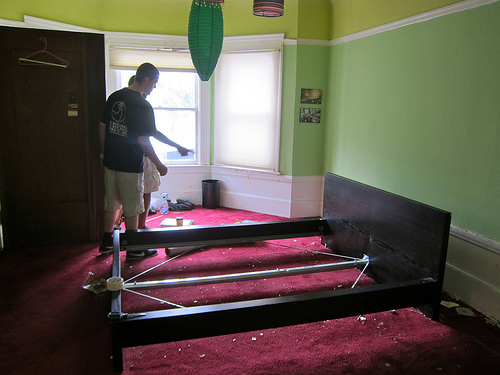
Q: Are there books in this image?
A: No, there are no books.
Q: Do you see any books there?
A: No, there are no books.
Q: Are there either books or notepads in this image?
A: No, there are no books or notepads.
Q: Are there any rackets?
A: No, there are no rackets.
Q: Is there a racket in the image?
A: No, there are no rackets.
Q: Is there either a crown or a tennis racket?
A: No, there are no rackets or crowns.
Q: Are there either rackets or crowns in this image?
A: No, there are no rackets or crowns.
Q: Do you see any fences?
A: No, there are no fences.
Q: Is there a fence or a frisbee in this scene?
A: No, there are no fences or frisbees.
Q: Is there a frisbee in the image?
A: No, there are no frisbees.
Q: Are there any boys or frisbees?
A: No, there are no frisbees or boys.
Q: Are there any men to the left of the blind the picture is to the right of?
A: Yes, there is a man to the left of the blind.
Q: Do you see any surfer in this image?
A: No, there are no surfers.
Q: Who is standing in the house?
A: The man is standing in the house.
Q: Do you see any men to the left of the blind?
A: Yes, there is a man to the left of the blind.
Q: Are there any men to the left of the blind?
A: Yes, there is a man to the left of the blind.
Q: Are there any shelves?
A: No, there are no shelves.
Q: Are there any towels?
A: No, there are no towels.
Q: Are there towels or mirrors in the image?
A: No, there are no towels or mirrors.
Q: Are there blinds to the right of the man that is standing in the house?
A: Yes, there is a blind to the right of the man.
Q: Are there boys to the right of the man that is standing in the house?
A: No, there is a blind to the right of the man.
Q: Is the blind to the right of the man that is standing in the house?
A: Yes, the blind is to the right of the man.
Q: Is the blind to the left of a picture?
A: Yes, the blind is to the left of a picture.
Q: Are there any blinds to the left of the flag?
A: Yes, there is a blind to the left of the flag.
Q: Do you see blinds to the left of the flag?
A: Yes, there is a blind to the left of the flag.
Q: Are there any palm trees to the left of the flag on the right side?
A: No, there is a blind to the left of the flag.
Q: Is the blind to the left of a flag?
A: Yes, the blind is to the left of a flag.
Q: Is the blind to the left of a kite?
A: No, the blind is to the left of a flag.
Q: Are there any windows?
A: Yes, there is a window.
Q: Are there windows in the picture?
A: Yes, there is a window.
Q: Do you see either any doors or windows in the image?
A: Yes, there is a window.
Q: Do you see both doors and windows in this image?
A: Yes, there are both a window and a door.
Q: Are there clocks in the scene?
A: No, there are no clocks.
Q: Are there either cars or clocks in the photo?
A: No, there are no clocks or cars.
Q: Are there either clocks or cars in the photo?
A: No, there are no clocks or cars.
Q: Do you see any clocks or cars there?
A: No, there are no clocks or cars.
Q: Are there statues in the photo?
A: No, there are no statues.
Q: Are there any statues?
A: No, there are no statues.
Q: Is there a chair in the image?
A: No, there are no chairs.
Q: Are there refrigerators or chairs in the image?
A: No, there are no chairs or refrigerators.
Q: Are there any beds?
A: Yes, there is a bed.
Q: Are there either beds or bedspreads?
A: Yes, there is a bed.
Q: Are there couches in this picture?
A: No, there are no couches.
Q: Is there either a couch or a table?
A: No, there are no couches or tables.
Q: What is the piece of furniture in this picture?
A: The piece of furniture is a bed.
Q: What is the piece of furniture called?
A: The piece of furniture is a bed.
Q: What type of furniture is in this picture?
A: The furniture is a bed.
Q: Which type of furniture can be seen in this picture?
A: The furniture is a bed.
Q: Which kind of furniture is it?
A: The piece of furniture is a bed.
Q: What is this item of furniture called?
A: This is a bed.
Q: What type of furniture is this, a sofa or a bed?
A: This is a bed.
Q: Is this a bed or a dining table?
A: This is a bed.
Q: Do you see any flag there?
A: Yes, there is a flag.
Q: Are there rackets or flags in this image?
A: Yes, there is a flag.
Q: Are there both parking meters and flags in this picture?
A: No, there is a flag but no parking meters.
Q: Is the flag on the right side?
A: Yes, the flag is on the right of the image.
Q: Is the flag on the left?
A: No, the flag is on the right of the image.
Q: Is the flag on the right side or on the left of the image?
A: The flag is on the right of the image.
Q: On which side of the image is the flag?
A: The flag is on the right of the image.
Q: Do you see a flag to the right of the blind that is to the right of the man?
A: Yes, there is a flag to the right of the blind.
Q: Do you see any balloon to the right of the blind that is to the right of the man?
A: No, there is a flag to the right of the blind.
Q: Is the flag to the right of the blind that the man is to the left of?
A: Yes, the flag is to the right of the blind.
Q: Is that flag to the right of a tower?
A: No, the flag is to the right of the blind.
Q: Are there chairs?
A: No, there are no chairs.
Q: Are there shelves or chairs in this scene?
A: No, there are no chairs or shelves.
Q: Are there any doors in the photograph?
A: Yes, there is a door.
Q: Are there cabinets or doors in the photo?
A: Yes, there is a door.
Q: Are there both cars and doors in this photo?
A: No, there is a door but no cars.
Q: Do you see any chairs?
A: No, there are no chairs.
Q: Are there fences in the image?
A: No, there are no fences.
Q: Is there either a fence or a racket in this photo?
A: No, there are no fences or rackets.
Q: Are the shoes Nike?
A: Yes, the shoes are nike.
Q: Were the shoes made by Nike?
A: Yes, the shoes were made by nike.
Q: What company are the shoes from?
A: The shoes are from nike.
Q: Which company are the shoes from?
A: The shoes are from nike.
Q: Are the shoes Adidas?
A: No, the shoes are nike.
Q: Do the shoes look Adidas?
A: No, the shoes are nike.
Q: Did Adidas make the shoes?
A: No, the shoes were made by nike.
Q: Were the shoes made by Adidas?
A: No, the shoes were made by nike.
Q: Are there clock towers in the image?
A: No, there are no clock towers.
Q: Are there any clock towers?
A: No, there are no clock towers.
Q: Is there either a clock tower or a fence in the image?
A: No, there are no clock towers or fences.